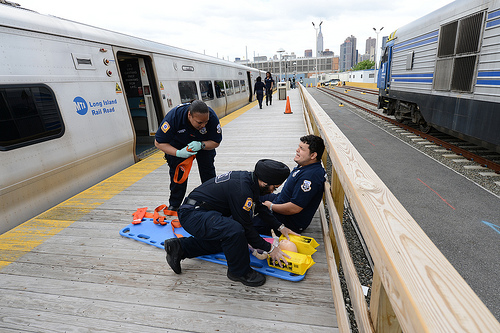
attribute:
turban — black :
[245, 152, 290, 184]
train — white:
[88, 25, 278, 100]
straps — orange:
[129, 198, 186, 236]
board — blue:
[113, 207, 311, 294]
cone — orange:
[283, 92, 291, 114]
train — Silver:
[31, 0, 308, 160]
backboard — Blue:
[118, 214, 309, 280]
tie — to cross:
[440, 150, 463, 160]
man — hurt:
[259, 132, 326, 235]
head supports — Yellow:
[269, 232, 324, 279]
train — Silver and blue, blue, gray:
[379, 0, 499, 155]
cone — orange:
[283, 99, 295, 116]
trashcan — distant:
[276, 84, 286, 99]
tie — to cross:
[259, 177, 299, 216]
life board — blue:
[121, 216, 307, 282]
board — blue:
[135, 189, 389, 326]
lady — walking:
[248, 70, 270, 113]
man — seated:
[263, 120, 323, 262]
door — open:
[113, 45, 180, 177]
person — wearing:
[159, 105, 239, 161]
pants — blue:
[161, 199, 289, 267]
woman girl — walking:
[247, 69, 278, 113]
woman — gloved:
[137, 93, 242, 221]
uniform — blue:
[160, 116, 190, 143]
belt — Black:
[182, 197, 204, 207]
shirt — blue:
[273, 162, 326, 232]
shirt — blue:
[188, 169, 283, 254]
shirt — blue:
[153, 103, 223, 150]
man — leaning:
[293, 133, 325, 191]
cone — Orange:
[283, 96, 290, 113]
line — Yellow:
[1, 84, 281, 274]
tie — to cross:
[409, 135, 421, 145]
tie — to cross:
[461, 162, 484, 172]